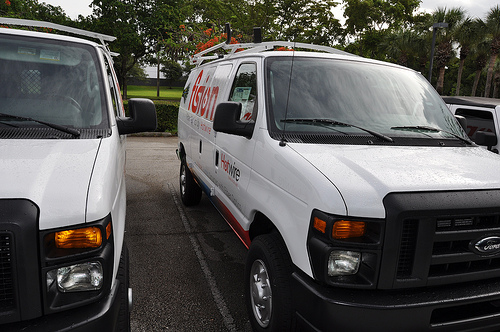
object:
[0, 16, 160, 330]
trucks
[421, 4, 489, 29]
shower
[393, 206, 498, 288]
grill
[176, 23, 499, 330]
truck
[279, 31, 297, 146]
antenna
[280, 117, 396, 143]
windshield wipers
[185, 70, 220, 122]
writing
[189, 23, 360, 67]
rack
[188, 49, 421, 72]
roof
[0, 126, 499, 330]
parking lot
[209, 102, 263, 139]
mirror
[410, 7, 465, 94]
trees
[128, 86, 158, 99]
grass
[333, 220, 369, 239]
light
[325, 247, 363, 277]
headlight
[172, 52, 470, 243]
van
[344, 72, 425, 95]
light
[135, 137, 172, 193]
blacktop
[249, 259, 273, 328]
hubcap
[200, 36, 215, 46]
flowers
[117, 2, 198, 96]
tree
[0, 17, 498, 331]
lot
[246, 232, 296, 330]
wheel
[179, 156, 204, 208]
wheel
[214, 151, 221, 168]
door handle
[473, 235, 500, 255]
logo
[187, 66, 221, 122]
lettering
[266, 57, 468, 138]
window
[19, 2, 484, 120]
background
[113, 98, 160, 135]
hedges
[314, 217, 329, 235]
turn signal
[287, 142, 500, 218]
hood